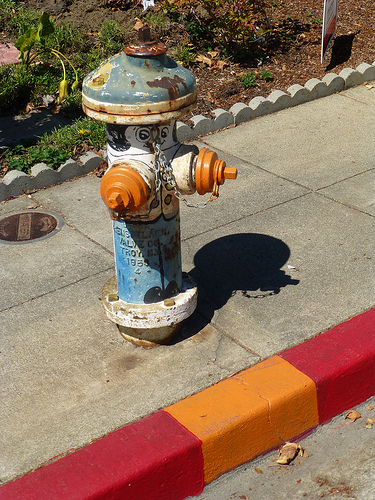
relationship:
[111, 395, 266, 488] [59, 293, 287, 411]
paints on pavement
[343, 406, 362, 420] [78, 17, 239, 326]
leaves on ground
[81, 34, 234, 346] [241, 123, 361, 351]
fire hydrant on sidewalk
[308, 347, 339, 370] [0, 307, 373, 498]
paint on sidewalk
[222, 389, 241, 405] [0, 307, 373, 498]
paint on sidewalk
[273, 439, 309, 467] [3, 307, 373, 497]
leaf along curb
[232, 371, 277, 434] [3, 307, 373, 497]
crack in curb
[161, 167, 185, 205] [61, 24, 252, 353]
chain on hydrant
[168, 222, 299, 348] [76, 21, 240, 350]
shadow from fire hydrant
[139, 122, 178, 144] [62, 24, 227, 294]
eyes on hydrant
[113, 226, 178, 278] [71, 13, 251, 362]
engraving on side of hydrant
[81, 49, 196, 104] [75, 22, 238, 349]
cap on hydrant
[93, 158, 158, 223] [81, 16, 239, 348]
side of fire hydrant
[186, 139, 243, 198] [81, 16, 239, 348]
side of fire hydrant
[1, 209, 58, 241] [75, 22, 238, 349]
brown pipe behind hydrant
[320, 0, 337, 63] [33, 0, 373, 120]
sign stuck in dirt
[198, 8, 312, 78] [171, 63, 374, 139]
dirt behind dividers